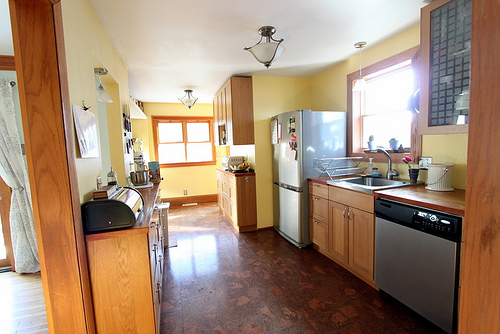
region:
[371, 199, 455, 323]
The dishwasher next to the cabinets.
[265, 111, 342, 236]
The fridge next to the wall.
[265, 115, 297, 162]
The magnets on the fridge.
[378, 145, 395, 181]
The faucet of the sink.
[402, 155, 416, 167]
The flower in the vase.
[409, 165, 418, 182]
The cup the flower is in.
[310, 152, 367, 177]
The silver dish drain.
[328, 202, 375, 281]
The cabinets below the sink.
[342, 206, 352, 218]
The door handles of the cabinet doors below the sink.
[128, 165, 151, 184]
The silver bowl on the counter.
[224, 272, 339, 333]
the floor is brown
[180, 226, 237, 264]
light is on the ground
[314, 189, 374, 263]
the cabinets are wooden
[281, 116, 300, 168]
stickers are on the fridge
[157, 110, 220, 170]
light is coming thruough the window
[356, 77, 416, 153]
light is coming through the window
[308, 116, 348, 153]
light reflection is on the table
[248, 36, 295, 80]
light is on the ceiling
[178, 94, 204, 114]
light is on the ceiling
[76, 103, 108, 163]
picture is on the wall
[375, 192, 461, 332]
washing machine gray and black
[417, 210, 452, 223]
the knobs are silver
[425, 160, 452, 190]
white pot on counter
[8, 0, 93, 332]
wall panel made of wood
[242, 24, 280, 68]
light hangs from ceiling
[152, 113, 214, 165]
window in rear of kitchen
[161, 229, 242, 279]
reflection on the floor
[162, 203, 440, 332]
the floor is brown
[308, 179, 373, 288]
cabinets made of wood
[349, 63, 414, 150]
sunlight coming from window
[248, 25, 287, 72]
a light on a kitchen ceiling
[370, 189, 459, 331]
a grey and black dishwasher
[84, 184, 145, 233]
a breadbox on a counter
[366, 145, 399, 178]
a faucet at a sink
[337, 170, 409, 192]
a metal kitchen sink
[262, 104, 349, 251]
a refrigerator in a kitchen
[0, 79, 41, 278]
a curtain in a window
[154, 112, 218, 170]
a widow in a dining room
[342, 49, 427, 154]
a kitchen window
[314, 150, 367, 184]
a white dish drying rack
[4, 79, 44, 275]
The white curtain in the next room.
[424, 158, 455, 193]
The white pail on the counter.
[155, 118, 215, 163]
The window in the room.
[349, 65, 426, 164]
The window over the sink.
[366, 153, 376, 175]
The soap dispenser.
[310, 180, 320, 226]
The handles of the drawers next to the fridge.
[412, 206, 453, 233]
The panel of buttons on the dishwasher.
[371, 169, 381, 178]
The sponge next to the sink.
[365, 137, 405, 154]
The plants on the window sill.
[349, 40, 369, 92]
The hanging lamp above the sink.